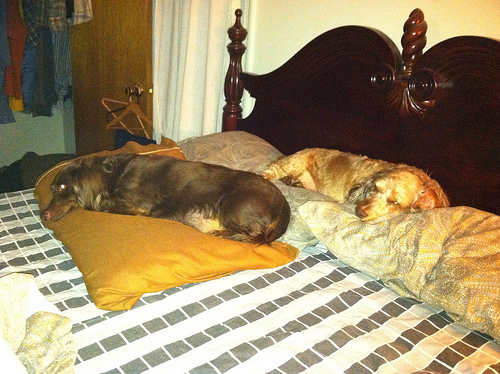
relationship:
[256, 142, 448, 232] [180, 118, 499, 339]
dog on pillow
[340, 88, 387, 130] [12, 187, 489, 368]
wood on bed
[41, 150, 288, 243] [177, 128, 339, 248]
dog on pillow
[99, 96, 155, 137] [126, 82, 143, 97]
hangers on doorknob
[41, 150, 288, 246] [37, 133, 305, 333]
dog on pillow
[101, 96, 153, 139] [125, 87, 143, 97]
hangers on doorknob